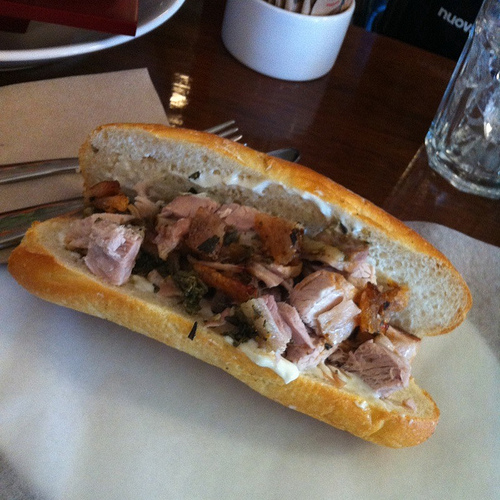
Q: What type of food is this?
A: Sandwich.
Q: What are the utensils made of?
A: Metal.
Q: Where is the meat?
A: In a sandwich.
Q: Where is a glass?
A: On the table.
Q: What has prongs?
A: The fork.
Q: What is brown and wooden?
A: Table.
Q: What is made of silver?
A: Fork and knife.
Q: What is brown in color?
A: Napkin.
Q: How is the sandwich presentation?
A: Top of paper on a plate.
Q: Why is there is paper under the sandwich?
A: To hold the sandwich.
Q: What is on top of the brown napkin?
A: Knife and fork.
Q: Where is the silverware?
A: Top of a napkin.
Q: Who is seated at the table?
A: A customer.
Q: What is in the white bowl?
A: Packages of sugar.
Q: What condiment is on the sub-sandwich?
A: Mayonnaise.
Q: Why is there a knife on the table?
A: To cut the sandwich.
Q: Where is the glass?
A: Top of a wooden table.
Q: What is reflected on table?
A: Light.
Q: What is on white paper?
A: A sandwich.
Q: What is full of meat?
A: The sandwich.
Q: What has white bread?
A: The sub.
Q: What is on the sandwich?
A: Mayonnaise.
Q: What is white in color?
A: The plate.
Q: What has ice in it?
A: A glass.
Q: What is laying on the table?
A: The silverware.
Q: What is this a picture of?
A: A submarine sandwich.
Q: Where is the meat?
A: In the roll.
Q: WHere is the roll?
A: On a table.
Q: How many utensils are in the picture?
A: 2.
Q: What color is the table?
A: Dark brown.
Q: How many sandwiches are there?
A: 1.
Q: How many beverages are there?
A: One.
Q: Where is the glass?
A: To the top right.